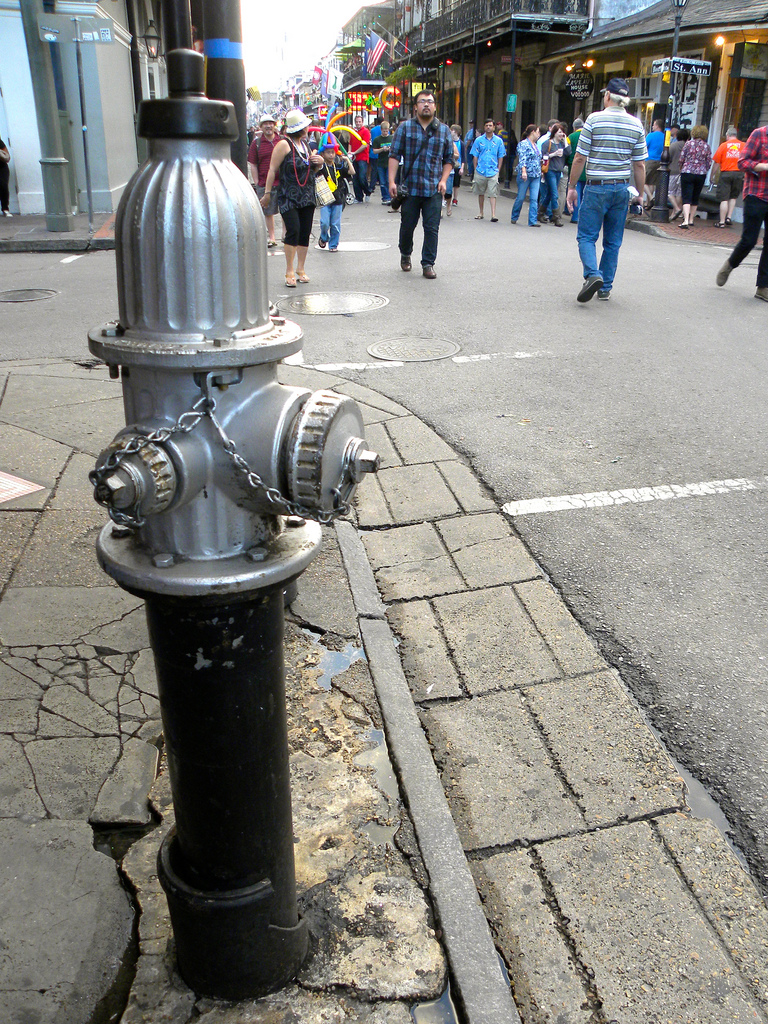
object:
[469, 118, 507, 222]
person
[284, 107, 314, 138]
hat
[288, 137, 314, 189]
necklace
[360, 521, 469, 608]
tile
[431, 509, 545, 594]
tile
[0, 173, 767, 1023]
floor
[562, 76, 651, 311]
man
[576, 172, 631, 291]
blue jeans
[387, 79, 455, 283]
people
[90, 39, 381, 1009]
hydrant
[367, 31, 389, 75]
flag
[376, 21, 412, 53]
pole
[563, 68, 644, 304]
person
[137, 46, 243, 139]
tip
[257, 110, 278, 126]
hat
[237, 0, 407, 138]
sky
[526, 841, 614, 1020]
lines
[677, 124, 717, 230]
person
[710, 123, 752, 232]
person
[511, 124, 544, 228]
person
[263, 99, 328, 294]
person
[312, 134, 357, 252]
person